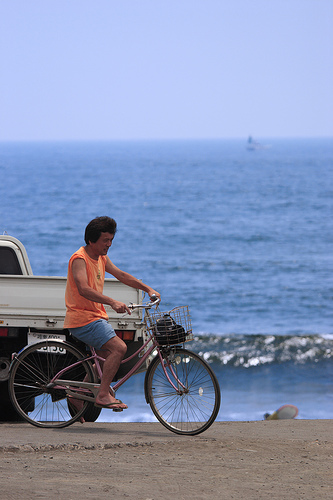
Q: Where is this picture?
A: The beach.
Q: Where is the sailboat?
A: In the distance.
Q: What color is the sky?
A: Blue.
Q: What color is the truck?
A: White.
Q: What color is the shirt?
A: Orange.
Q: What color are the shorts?
A: Light blue.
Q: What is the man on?
A: Bike.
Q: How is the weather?
A: Warm.